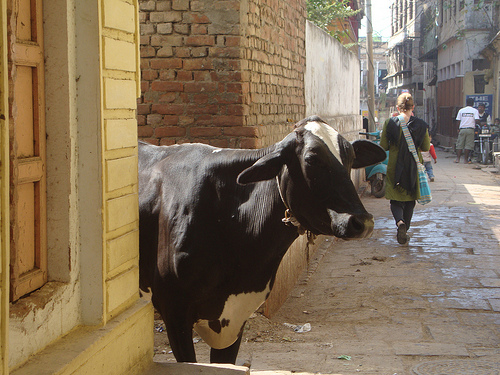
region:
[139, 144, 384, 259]
A cow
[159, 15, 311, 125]
A brick building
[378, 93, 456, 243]
A lady walking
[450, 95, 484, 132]
A person wearing a white shirt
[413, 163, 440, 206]
Lady carrying a stripped bag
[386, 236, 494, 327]
the ground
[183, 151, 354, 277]
a cow standing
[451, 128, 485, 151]
man wearing shorts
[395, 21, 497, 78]
A buildign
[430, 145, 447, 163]
A persons arm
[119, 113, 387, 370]
a black and white cow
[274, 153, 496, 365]
a cobble stone street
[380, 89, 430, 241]
a pedestrian walking street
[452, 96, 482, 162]
pedestrian standing on street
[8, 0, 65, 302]
an orange inset doorway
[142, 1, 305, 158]
a red brick wall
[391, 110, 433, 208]
a multicolored over the shoulder bag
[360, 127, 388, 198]
a light blue motorcycle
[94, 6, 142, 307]
a yellow brick wall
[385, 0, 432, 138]
a white building in distance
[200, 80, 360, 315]
a black and white cow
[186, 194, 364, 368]
a black and white cow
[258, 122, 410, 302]
a black and white cow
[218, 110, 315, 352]
a black and white cow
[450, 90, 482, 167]
man standing in alley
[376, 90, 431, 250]
woman walking in alley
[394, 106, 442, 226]
bag that woman is carrying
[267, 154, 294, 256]
rope around cow's neck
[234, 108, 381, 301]
cow sticking head in alley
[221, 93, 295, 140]
bricks in the alley wall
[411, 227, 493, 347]
pavement bricks on alley floor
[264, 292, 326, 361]
trash on alley ground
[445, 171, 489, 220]
shadow of buildings on alley floor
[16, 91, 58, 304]
shutter of window in building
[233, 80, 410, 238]
the head is white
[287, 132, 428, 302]
the head is white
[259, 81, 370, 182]
the head is white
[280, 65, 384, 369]
the head is white